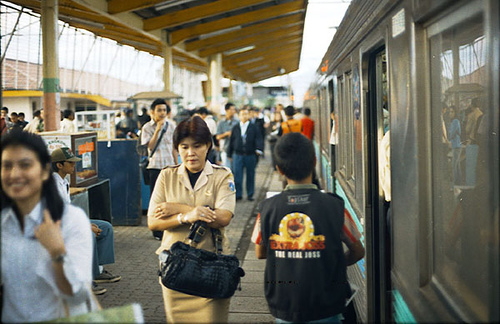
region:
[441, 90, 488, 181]
people reflected in window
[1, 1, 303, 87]
yellow wooden awning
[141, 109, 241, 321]
woman in beige suit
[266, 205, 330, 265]
yellow and orange logo on black vest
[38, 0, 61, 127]
green stripe around wooden pole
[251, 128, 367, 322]
boy with red striped sleeves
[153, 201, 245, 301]
woman holding black handbag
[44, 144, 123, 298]
boy in brown cap sitting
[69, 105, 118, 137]
white railing in left background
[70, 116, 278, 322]
gray cobblestone sidewalk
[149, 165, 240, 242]
woman's shirt is brown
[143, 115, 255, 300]
woman carrying a black bag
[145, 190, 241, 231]
woman's arms are crossed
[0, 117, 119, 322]
the woman is smiling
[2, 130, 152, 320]
woman carrying a purse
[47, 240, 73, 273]
woman wearing a watch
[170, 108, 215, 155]
woman's hair is brown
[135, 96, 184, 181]
man wearing a shoulder bag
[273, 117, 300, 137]
man's shirt is orange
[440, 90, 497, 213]
reflection of people on the window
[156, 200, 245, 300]
Woman holding a purse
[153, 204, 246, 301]
Woman is holding a purse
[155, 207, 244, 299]
Woman holding a black purse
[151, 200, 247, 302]
Woman is holding a black purse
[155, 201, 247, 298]
Woman carrying a purse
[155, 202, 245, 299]
Woman is carrying a purse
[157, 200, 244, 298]
Woman carrying a black purse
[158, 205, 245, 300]
Woman is carrying a black purse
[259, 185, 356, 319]
Boy wearing a vest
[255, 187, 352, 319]
Boy is wearing a vest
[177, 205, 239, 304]
Person carrying black bag.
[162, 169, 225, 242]
Person wearing tan shirt.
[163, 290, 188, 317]
Person wearing tan skirt.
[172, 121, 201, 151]
Person has dark hair.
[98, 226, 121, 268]
Person wearing blue pants.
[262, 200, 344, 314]
Person wearing black vest.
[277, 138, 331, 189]
Person has short dark hair.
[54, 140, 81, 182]
Person wearing hat on head.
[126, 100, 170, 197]
Person has bag over shoulder.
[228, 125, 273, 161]
Person wearing black coat.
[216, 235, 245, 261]
aprt of a hanle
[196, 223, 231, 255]
part of a handle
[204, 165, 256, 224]
part of a sleeve